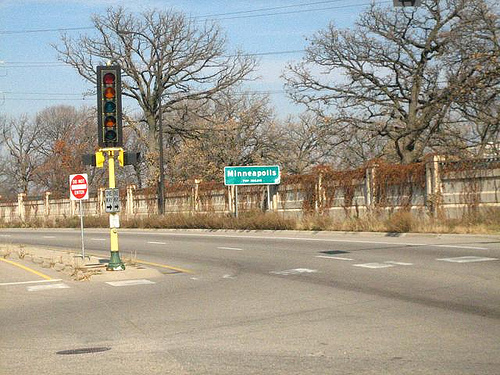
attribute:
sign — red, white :
[70, 170, 90, 202]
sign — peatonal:
[115, 137, 150, 164]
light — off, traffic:
[91, 61, 128, 155]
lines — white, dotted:
[139, 225, 264, 272]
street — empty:
[0, 227, 499, 374]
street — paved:
[211, 240, 373, 334]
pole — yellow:
[102, 149, 121, 254]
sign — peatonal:
[223, 137, 286, 194]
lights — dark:
[103, 72, 116, 142]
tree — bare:
[41, 2, 273, 215]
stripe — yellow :
[2, 251, 62, 301]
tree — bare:
[53, 4, 263, 185]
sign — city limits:
[221, 161, 281, 219]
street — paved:
[2, 230, 497, 349]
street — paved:
[190, 237, 348, 299]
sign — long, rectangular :
[181, 135, 298, 227]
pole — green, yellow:
[91, 149, 131, 279]